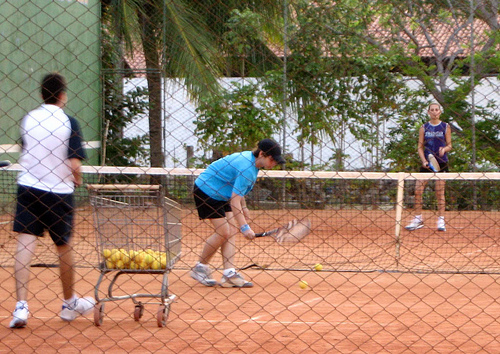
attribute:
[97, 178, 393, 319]
tennis — played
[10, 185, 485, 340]
court — tennis, tan, clay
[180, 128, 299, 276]
man — playing tennis, practicing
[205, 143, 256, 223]
shirt — blue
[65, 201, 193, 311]
cart — shopping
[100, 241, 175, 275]
balls — yellow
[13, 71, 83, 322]
man — standing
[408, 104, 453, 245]
woman — waiting, playing tennis, young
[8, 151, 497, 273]
net — low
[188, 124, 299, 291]
boy — light-skinned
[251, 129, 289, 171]
cap — black, protection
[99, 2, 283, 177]
tree — green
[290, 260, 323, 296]
ball — yellow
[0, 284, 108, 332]
shoes — white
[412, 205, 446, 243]
shoes — white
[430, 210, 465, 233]
shoe — white